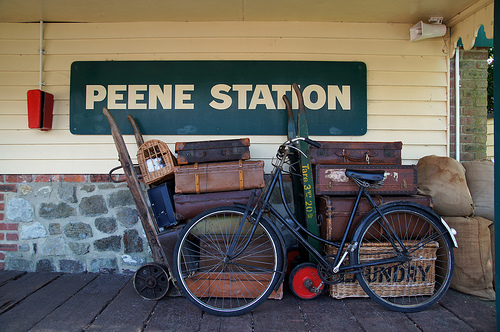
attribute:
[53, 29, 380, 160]
sign — green, white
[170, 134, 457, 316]
bicycle — shiny, black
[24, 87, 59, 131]
object — red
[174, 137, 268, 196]
suitcase — light brown, leather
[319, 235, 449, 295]
basket — light brown, wicker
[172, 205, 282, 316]
tire — black, rubber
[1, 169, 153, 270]
stone wall — gray, red, brick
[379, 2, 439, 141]
siding — yellow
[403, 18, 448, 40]
loud speaker — white, plastic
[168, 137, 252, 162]
suitcase — dark, brown, leather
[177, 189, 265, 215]
suitcase — dark, brown, leather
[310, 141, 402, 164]
suitcase — dark, brown, leather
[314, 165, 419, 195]
suitcase — dark, brown, leather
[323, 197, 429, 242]
suitcase — dark, brown, leather